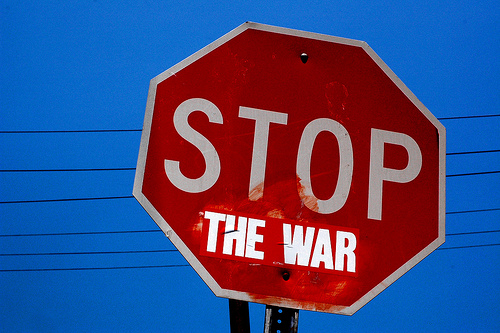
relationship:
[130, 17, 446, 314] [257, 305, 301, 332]
stop sign attached to pole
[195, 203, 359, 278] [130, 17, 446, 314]
sticker stuck on stop sign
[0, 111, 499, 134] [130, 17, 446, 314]
power line behind stop sign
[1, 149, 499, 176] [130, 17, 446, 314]
power line behind stop sign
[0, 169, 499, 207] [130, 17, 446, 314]
power line behind stop sign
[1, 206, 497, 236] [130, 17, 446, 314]
power line behind stop sign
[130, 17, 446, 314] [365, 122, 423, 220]
stop sign painted with letter p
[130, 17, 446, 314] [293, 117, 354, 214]
stop sign painted with letter o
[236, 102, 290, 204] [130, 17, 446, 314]
letter t painted on stop sign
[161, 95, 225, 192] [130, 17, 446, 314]
letter s painted on stop sign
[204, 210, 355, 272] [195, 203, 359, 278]
letters on sticker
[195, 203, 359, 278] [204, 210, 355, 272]
sticker has letters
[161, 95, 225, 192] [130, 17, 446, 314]
letter s on stop sign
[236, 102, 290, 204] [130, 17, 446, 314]
letter t on stop sign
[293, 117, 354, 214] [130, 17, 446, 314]
letter o on stop sign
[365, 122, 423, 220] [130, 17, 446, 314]
letter p on stop sign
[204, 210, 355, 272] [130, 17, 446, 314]
letters on stop sign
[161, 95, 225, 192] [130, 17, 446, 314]
letter s printed on stop sign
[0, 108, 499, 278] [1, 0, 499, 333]
telephone lines in sky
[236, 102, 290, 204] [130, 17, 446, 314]
letter t printed on stop sign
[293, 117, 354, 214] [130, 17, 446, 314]
letter o printed on stop sign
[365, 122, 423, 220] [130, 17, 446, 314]
letter p printed on stop sign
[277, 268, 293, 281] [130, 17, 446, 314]
bolt securing stop sign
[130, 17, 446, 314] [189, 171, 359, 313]
stop sign has signs of vandalism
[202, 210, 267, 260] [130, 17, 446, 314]
word added to stop sign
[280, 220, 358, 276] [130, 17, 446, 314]
word added to stop sign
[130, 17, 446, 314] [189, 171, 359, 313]
stop sign with vandalism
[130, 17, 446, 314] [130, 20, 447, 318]
stop sign has white trim